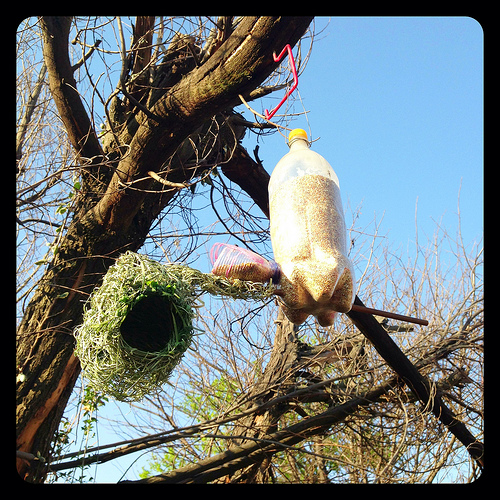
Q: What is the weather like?
A: It is clear.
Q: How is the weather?
A: It is clear.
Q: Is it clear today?
A: Yes, it is clear.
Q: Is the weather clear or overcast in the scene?
A: It is clear.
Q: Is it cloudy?
A: No, it is clear.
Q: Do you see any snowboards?
A: No, there are no snowboards.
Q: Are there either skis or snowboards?
A: No, there are no snowboards or skis.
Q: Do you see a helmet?
A: No, there are no helmets.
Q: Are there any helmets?
A: No, there are no helmets.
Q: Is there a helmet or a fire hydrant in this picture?
A: No, there are no helmets or fire hydrants.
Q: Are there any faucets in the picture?
A: No, there are no faucets.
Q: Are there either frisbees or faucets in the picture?
A: No, there are no faucets or frisbees.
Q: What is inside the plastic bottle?
A: The seed is inside the bottle.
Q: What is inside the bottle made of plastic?
A: The seed is inside the bottle.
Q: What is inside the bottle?
A: The seed is inside the bottle.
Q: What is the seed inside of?
A: The seed is inside the bottle.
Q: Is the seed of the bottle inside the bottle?
A: Yes, the seed is inside the bottle.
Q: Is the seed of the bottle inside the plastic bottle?
A: Yes, the seed is inside the bottle.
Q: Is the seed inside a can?
A: No, the seed is inside the bottle.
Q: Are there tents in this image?
A: No, there are no tents.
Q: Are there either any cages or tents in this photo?
A: No, there are no tents or cages.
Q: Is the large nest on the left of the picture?
A: Yes, the nest is on the left of the image.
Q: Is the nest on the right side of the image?
A: No, the nest is on the left of the image.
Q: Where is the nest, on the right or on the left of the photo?
A: The nest is on the left of the image.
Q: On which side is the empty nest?
A: The nest is on the left of the image.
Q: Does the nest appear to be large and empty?
A: Yes, the nest is large and empty.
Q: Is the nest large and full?
A: No, the nest is large but empty.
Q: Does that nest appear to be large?
A: Yes, the nest is large.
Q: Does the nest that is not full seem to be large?
A: Yes, the nest is large.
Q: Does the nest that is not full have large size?
A: Yes, the nest is large.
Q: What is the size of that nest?
A: The nest is large.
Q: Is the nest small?
A: No, the nest is large.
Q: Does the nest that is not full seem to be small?
A: No, the nest is large.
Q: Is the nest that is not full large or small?
A: The nest is large.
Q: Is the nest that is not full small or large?
A: The nest is large.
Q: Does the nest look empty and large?
A: Yes, the nest is empty and large.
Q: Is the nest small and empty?
A: No, the nest is empty but large.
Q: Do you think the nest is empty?
A: Yes, the nest is empty.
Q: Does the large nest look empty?
A: Yes, the nest is empty.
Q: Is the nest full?
A: No, the nest is empty.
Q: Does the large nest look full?
A: No, the nest is empty.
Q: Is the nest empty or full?
A: The nest is empty.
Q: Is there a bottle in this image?
A: Yes, there is a bottle.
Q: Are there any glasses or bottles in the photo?
A: Yes, there is a bottle.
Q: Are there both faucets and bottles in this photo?
A: No, there is a bottle but no faucets.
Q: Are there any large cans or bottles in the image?
A: Yes, there is a large bottle.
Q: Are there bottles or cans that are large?
A: Yes, the bottle is large.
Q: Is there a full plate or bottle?
A: Yes, there is a full bottle.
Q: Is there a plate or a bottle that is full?
A: Yes, the bottle is full.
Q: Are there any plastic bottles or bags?
A: Yes, there is a plastic bottle.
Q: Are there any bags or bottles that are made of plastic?
A: Yes, the bottle is made of plastic.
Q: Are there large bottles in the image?
A: Yes, there is a large bottle.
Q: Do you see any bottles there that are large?
A: Yes, there is a bottle that is large.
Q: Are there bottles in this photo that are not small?
A: Yes, there is a large bottle.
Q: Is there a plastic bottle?
A: Yes, there is a bottle that is made of plastic.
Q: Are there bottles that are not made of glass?
A: Yes, there is a bottle that is made of plastic.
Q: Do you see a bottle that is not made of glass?
A: Yes, there is a bottle that is made of plastic.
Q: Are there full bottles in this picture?
A: Yes, there is a full bottle.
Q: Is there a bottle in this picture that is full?
A: Yes, there is a bottle that is full.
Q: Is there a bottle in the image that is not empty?
A: Yes, there is an full bottle.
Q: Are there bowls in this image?
A: No, there are no bowls.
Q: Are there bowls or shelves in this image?
A: No, there are no bowls or shelves.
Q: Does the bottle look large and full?
A: Yes, the bottle is large and full.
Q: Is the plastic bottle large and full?
A: Yes, the bottle is large and full.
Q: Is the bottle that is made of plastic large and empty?
A: No, the bottle is large but full.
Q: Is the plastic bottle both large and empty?
A: No, the bottle is large but full.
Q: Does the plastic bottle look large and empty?
A: No, the bottle is large but full.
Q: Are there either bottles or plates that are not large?
A: No, there is a bottle but it is large.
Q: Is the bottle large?
A: Yes, the bottle is large.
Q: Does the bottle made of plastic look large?
A: Yes, the bottle is large.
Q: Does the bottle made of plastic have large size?
A: Yes, the bottle is large.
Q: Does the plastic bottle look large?
A: Yes, the bottle is large.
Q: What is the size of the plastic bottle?
A: The bottle is large.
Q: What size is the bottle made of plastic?
A: The bottle is large.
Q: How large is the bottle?
A: The bottle is large.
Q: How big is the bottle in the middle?
A: The bottle is large.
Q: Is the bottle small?
A: No, the bottle is large.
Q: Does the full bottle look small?
A: No, the bottle is large.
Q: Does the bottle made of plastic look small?
A: No, the bottle is large.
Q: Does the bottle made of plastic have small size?
A: No, the bottle is large.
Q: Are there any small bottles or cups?
A: No, there is a bottle but it is large.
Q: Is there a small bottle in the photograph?
A: No, there is a bottle but it is large.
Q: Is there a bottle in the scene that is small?
A: No, there is a bottle but it is large.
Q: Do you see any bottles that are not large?
A: No, there is a bottle but it is large.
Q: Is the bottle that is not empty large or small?
A: The bottle is large.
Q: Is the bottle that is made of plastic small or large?
A: The bottle is large.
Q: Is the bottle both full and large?
A: Yes, the bottle is full and large.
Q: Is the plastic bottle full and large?
A: Yes, the bottle is full and large.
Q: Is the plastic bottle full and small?
A: No, the bottle is full but large.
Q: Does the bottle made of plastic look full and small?
A: No, the bottle is full but large.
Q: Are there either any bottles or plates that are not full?
A: No, there is a bottle but it is full.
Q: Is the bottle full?
A: Yes, the bottle is full.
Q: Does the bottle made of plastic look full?
A: Yes, the bottle is full.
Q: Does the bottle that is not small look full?
A: Yes, the bottle is full.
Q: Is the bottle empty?
A: No, the bottle is full.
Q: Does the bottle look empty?
A: No, the bottle is full.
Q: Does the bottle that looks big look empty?
A: No, the bottle is full.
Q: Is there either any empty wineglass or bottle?
A: No, there is a bottle but it is full.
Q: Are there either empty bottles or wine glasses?
A: No, there is a bottle but it is full.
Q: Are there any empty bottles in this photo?
A: No, there is a bottle but it is full.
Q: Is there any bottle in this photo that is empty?
A: No, there is a bottle but it is full.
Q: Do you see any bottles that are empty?
A: No, there is a bottle but it is full.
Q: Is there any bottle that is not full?
A: No, there is a bottle but it is full.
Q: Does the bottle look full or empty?
A: The bottle is full.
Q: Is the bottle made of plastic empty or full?
A: The bottle is full.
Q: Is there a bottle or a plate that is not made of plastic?
A: No, there is a bottle but it is made of plastic.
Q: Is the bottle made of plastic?
A: Yes, the bottle is made of plastic.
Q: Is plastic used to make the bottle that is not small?
A: Yes, the bottle is made of plastic.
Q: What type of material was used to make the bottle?
A: The bottle is made of plastic.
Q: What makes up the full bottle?
A: The bottle is made of plastic.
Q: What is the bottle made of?
A: The bottle is made of plastic.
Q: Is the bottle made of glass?
A: No, the bottle is made of plastic.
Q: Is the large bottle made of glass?
A: No, the bottle is made of plastic.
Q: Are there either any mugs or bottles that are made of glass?
A: No, there is a bottle but it is made of plastic.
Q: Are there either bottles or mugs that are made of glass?
A: No, there is a bottle but it is made of plastic.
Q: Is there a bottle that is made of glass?
A: No, there is a bottle but it is made of plastic.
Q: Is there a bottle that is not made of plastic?
A: No, there is a bottle but it is made of plastic.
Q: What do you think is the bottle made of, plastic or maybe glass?
A: The bottle is made of plastic.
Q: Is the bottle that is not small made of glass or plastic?
A: The bottle is made of plastic.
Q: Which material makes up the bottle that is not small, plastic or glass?
A: The bottle is made of plastic.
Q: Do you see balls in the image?
A: No, there are no balls.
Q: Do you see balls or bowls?
A: No, there are no balls or bowls.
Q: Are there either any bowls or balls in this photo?
A: No, there are no balls or bowls.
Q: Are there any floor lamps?
A: No, there are no floor lamps.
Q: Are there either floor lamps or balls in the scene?
A: No, there are no floor lamps or balls.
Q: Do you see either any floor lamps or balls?
A: No, there are no floor lamps or balls.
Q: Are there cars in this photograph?
A: No, there are no cars.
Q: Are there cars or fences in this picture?
A: No, there are no cars or fences.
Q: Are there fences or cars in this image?
A: No, there are no cars or fences.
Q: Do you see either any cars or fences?
A: No, there are no cars or fences.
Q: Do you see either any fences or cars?
A: No, there are no cars or fences.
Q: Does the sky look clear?
A: Yes, the sky is clear.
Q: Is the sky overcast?
A: No, the sky is clear.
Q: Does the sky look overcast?
A: No, the sky is clear.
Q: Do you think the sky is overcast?
A: No, the sky is clear.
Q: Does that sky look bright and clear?
A: Yes, the sky is bright and clear.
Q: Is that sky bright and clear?
A: Yes, the sky is bright and clear.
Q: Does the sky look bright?
A: Yes, the sky is bright.